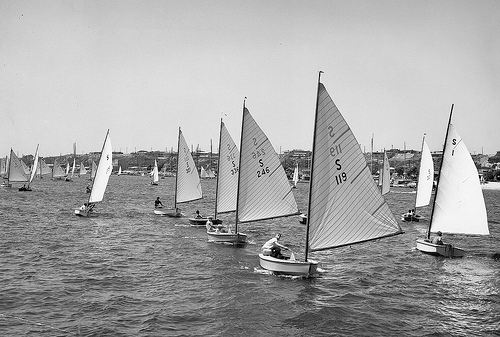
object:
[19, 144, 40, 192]
sailboats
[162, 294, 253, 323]
ocean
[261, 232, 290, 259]
man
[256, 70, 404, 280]
boat 119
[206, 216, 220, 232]
man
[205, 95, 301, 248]
boat 246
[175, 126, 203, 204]
sails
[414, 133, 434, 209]
sails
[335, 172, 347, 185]
numbers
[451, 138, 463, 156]
black letter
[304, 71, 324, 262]
mast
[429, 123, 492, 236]
sail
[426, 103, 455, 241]
pole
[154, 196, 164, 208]
person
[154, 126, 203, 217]
boat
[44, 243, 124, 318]
waves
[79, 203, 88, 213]
person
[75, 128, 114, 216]
sailboat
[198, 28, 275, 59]
sky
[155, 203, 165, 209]
dark top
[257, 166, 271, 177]
writing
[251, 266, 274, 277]
splashes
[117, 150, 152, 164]
land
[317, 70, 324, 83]
tip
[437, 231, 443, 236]
hat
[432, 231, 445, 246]
guy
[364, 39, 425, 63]
clouds